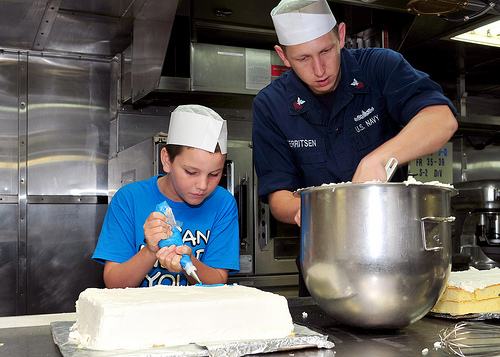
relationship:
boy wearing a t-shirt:
[93, 105, 240, 285] [93, 174, 240, 288]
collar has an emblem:
[283, 74, 313, 118] [294, 98, 305, 109]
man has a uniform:
[252, 3, 459, 296] [254, 45, 455, 203]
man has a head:
[252, 3, 459, 296] [273, 0, 346, 90]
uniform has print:
[254, 48, 455, 203] [354, 107, 380, 133]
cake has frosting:
[71, 285, 297, 346] [84, 283, 282, 314]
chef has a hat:
[254, 2, 463, 295] [166, 104, 228, 154]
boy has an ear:
[93, 105, 240, 285] [161, 145, 171, 176]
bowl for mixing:
[294, 180, 460, 330] [352, 158, 397, 183]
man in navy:
[252, 3, 459, 296] [357, 117, 383, 134]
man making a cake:
[252, 3, 459, 296] [71, 285, 297, 346]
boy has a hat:
[91, 105, 240, 289] [166, 104, 228, 154]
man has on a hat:
[252, 3, 459, 296] [166, 104, 228, 154]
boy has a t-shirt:
[93, 105, 240, 285] [93, 174, 240, 288]